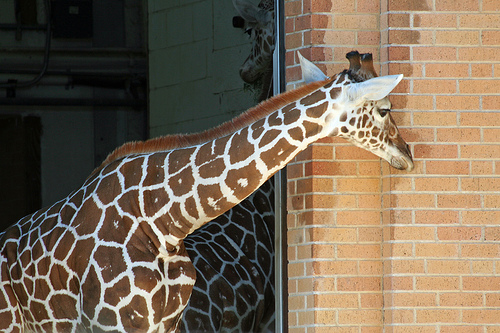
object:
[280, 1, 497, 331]
brick building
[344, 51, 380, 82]
ossicones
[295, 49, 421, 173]
giraffe head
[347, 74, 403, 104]
ear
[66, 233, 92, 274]
brown spots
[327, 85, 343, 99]
spot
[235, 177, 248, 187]
spots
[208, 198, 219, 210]
spots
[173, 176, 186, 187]
spots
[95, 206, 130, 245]
spots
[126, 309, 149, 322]
spots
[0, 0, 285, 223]
wall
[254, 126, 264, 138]
spot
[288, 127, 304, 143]
spot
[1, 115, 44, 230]
black door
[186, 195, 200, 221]
spot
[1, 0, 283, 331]
doorway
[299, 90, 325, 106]
spot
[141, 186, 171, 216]
spot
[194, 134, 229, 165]
spot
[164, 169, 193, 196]
spot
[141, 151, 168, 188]
spot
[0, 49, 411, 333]
animal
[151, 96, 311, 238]
neck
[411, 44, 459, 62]
red bricks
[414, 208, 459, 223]
red bricks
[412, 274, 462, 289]
red bricks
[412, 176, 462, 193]
red bricks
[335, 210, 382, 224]
red bricks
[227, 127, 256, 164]
spot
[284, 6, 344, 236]
stain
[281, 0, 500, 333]
wall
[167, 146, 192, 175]
spot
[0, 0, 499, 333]
wrong photo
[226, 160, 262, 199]
patch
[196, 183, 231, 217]
patch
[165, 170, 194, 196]
patch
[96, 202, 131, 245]
patch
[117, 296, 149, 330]
patch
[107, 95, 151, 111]
bridge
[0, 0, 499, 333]
building